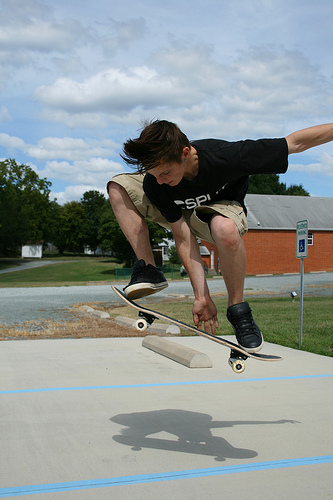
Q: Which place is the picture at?
A: It is at the parking lot.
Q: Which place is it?
A: It is a parking lot.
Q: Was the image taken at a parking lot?
A: Yes, it was taken in a parking lot.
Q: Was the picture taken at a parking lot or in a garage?
A: It was taken at a parking lot.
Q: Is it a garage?
A: No, it is a parking lot.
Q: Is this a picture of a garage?
A: No, the picture is showing a parking lot.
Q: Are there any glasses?
A: No, there are no glasses.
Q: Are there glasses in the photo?
A: No, there are no glasses.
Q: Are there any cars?
A: No, there are no cars.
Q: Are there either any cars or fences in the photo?
A: No, there are no cars or fences.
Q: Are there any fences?
A: No, there are no fences.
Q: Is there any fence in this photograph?
A: No, there are no fences.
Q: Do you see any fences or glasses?
A: No, there are no glasses or fences.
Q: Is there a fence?
A: No, there are no fences.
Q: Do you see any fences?
A: No, there are no fences.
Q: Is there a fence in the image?
A: No, there are no fences.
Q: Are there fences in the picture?
A: No, there are no fences.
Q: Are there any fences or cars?
A: No, there are no fences or cars.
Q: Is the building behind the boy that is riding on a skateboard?
A: Yes, the building is behind the boy.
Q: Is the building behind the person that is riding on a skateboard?
A: Yes, the building is behind the boy.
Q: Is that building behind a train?
A: No, the building is behind the boy.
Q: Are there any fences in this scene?
A: No, there are no fences.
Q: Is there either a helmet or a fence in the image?
A: No, there are no fences or helmets.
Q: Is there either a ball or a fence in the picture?
A: No, there are no fences or balls.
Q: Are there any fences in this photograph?
A: No, there are no fences.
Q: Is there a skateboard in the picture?
A: Yes, there is a skateboard.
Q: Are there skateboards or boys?
A: Yes, there is a skateboard.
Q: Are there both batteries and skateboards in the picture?
A: No, there is a skateboard but no batteries.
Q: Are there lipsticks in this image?
A: No, there are no lipsticks.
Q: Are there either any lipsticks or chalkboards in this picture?
A: No, there are no lipsticks or chalkboards.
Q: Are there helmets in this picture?
A: No, there are no helmets.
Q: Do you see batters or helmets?
A: No, there are no helmets or batters.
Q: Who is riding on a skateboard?
A: The boy is riding on a skateboard.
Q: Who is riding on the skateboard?
A: The boy is riding on a skateboard.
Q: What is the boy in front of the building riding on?
A: The boy is riding on a skateboard.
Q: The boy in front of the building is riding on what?
A: The boy is riding on a skateboard.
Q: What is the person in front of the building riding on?
A: The boy is riding on a skateboard.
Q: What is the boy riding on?
A: The boy is riding on a skateboard.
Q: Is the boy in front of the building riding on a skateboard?
A: Yes, the boy is riding on a skateboard.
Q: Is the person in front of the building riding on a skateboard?
A: Yes, the boy is riding on a skateboard.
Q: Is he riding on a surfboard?
A: No, the boy is riding on a skateboard.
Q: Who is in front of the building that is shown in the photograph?
A: The boy is in front of the building.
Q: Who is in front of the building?
A: The boy is in front of the building.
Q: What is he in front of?
A: The boy is in front of the building.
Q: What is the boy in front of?
A: The boy is in front of the building.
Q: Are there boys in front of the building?
A: Yes, there is a boy in front of the building.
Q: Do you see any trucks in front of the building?
A: No, there is a boy in front of the building.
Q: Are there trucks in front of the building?
A: No, there is a boy in front of the building.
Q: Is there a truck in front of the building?
A: No, there is a boy in front of the building.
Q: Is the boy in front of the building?
A: Yes, the boy is in front of the building.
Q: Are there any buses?
A: No, there are no buses.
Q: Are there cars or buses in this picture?
A: No, there are no buses or cars.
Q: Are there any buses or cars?
A: No, there are no buses or cars.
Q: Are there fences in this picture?
A: No, there are no fences.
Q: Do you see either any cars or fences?
A: No, there are no fences or cars.